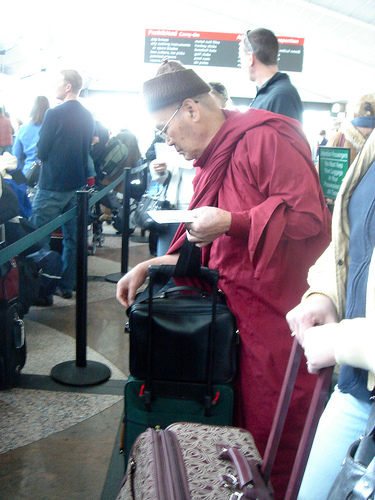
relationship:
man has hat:
[149, 58, 325, 491] [141, 61, 209, 112]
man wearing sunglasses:
[222, 11, 322, 114] [243, 29, 252, 51]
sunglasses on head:
[243, 29, 252, 51] [236, 25, 281, 89]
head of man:
[236, 25, 281, 89] [222, 11, 322, 114]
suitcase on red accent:
[118, 371, 234, 476] [136, 382, 148, 397]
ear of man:
[248, 52, 256, 65] [238, 26, 303, 127]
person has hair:
[10, 91, 54, 232] [28, 95, 49, 128]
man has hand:
[113, 60, 332, 497] [109, 259, 151, 307]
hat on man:
[140, 57, 203, 115] [113, 60, 332, 497]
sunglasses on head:
[241, 23, 254, 49] [232, 26, 281, 82]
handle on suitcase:
[219, 443, 259, 496] [116, 421, 282, 498]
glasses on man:
[155, 116, 170, 140] [132, 73, 330, 343]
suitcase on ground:
[118, 372, 237, 460] [0, 219, 155, 499]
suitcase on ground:
[118, 371, 234, 476] [0, 219, 155, 499]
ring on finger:
[289, 328, 298, 339] [288, 317, 296, 337]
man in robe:
[113, 60, 332, 497] [152, 107, 325, 435]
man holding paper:
[113, 60, 332, 497] [142, 207, 196, 227]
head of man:
[236, 25, 281, 89] [233, 24, 306, 127]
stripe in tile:
[43, 364, 118, 404] [1, 217, 159, 498]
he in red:
[115, 61, 329, 499] [263, 357, 281, 377]